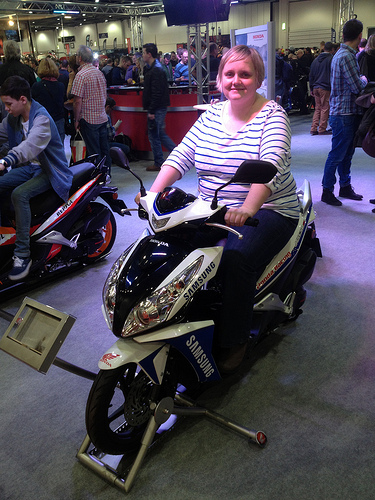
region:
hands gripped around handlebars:
[114, 176, 294, 242]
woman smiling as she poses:
[186, 22, 309, 264]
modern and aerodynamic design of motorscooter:
[80, 165, 345, 453]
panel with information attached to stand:
[2, 285, 122, 394]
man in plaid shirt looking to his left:
[315, 15, 369, 234]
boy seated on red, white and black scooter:
[0, 78, 90, 284]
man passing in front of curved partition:
[114, 23, 180, 164]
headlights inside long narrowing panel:
[112, 242, 205, 336]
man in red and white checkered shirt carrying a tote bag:
[58, 36, 124, 167]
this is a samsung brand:
[190, 332, 212, 381]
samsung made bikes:
[143, 236, 206, 375]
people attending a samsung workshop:
[37, 46, 241, 99]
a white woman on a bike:
[210, 64, 285, 222]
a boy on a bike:
[0, 84, 91, 222]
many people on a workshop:
[16, 37, 369, 129]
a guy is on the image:
[322, 33, 373, 170]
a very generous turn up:
[60, 35, 273, 118]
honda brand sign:
[252, 32, 268, 49]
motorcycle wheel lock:
[76, 343, 269, 481]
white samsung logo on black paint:
[183, 336, 222, 385]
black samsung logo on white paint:
[181, 260, 223, 306]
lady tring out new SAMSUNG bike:
[94, 36, 337, 356]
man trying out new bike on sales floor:
[0, 76, 122, 283]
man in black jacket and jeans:
[128, 40, 182, 169]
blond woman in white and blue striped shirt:
[152, 45, 357, 319]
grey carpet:
[303, 318, 373, 467]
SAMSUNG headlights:
[100, 228, 209, 339]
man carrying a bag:
[63, 49, 123, 183]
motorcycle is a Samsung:
[80, 257, 295, 484]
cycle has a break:
[23, 298, 233, 476]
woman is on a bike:
[142, 118, 373, 307]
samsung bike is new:
[87, 207, 316, 374]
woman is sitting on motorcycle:
[134, 114, 357, 319]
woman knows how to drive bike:
[122, 150, 340, 249]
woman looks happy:
[194, 49, 347, 156]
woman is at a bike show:
[238, 27, 374, 95]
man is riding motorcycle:
[9, 87, 134, 201]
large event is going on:
[30, 35, 274, 141]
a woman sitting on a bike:
[67, 40, 322, 456]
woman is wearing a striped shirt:
[145, 90, 316, 218]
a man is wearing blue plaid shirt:
[321, 18, 370, 229]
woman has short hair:
[193, 30, 287, 117]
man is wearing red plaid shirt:
[65, 40, 115, 143]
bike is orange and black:
[0, 144, 133, 273]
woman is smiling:
[224, 65, 254, 93]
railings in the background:
[0, 0, 166, 15]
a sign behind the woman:
[227, 22, 282, 102]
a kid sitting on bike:
[0, 72, 124, 287]